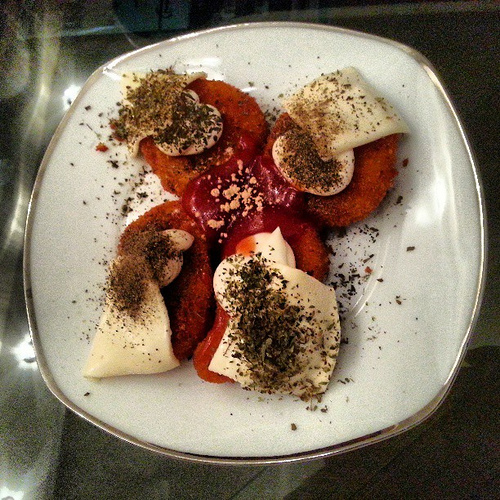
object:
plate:
[23, 20, 490, 469]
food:
[71, 43, 418, 427]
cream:
[235, 226, 299, 270]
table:
[1, 1, 498, 497]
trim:
[24, 20, 488, 467]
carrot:
[139, 77, 268, 198]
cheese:
[126, 70, 225, 158]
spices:
[113, 66, 224, 156]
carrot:
[196, 214, 331, 386]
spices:
[212, 245, 402, 398]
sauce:
[183, 130, 305, 259]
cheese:
[83, 227, 196, 377]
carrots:
[255, 99, 366, 212]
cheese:
[205, 227, 344, 402]